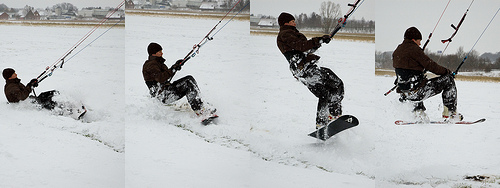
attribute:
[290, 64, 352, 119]
ski pants — black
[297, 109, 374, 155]
snowboard — black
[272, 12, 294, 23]
hat — black 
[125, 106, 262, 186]
snow — slushy, wet, deep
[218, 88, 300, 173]
snow — white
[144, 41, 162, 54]
hat — black